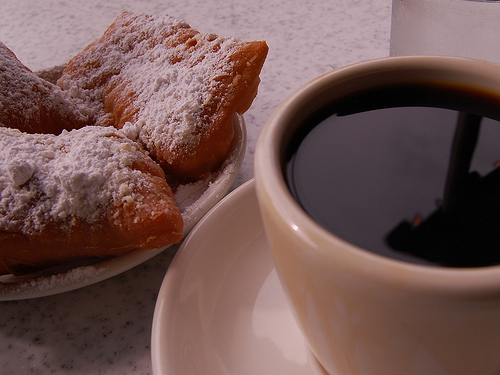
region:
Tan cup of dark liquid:
[256, 36, 499, 373]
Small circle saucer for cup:
[142, 185, 479, 373]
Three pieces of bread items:
[1, 10, 283, 281]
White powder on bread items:
[1, 23, 233, 239]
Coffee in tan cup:
[292, 67, 498, 284]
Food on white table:
[4, 2, 394, 374]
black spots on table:
[1, 0, 401, 374]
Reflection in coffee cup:
[389, 94, 498, 270]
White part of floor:
[396, 2, 499, 110]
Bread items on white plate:
[0, 77, 264, 289]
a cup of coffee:
[239, 36, 498, 372]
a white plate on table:
[142, 85, 497, 372]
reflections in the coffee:
[302, 82, 493, 243]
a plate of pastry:
[0, 9, 267, 286]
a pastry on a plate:
[3, 28, 266, 316]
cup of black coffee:
[226, 41, 498, 363]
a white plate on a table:
[130, 66, 496, 371]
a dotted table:
[35, 308, 127, 372]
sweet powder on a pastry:
[79, 33, 224, 135]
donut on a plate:
[63, 24, 265, 167]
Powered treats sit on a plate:
[0, 9, 266, 253]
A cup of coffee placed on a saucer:
[255, 48, 499, 373]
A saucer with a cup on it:
[142, 167, 329, 373]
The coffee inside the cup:
[275, 71, 495, 271]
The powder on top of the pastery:
[0, 126, 132, 218]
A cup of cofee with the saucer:
[137, 56, 498, 374]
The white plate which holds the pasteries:
[1, 117, 248, 308]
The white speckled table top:
[0, 1, 394, 373]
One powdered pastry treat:
[54, 15, 257, 175]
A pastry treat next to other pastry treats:
[0, 37, 76, 122]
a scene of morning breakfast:
[0, 1, 496, 372]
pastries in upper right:
[0, 64, 239, 257]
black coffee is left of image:
[287, 72, 498, 259]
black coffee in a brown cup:
[254, 225, 489, 370]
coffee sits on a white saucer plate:
[158, 219, 312, 372]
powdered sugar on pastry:
[1, 144, 123, 221]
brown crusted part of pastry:
[96, 209, 176, 253]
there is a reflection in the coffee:
[384, 105, 493, 256]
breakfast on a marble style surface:
[242, 0, 387, 63]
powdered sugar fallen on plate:
[6, 262, 106, 297]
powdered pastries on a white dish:
[0, 0, 266, 301]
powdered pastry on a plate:
[50, 5, 270, 175]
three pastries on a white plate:
[0, 0, 270, 305]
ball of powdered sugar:
[5, 152, 31, 182]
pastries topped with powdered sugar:
[0, 1, 270, 301]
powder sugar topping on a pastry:
[0, 121, 131, 213]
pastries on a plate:
[1, 6, 273, 304]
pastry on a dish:
[49, 6, 270, 176]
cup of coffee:
[251, 51, 498, 373]